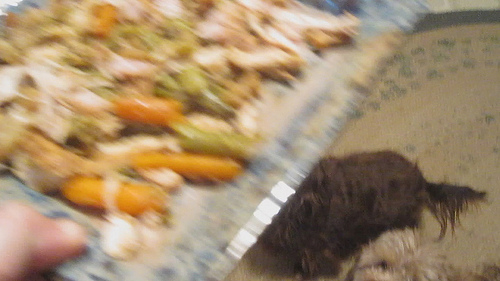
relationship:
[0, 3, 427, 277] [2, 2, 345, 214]
pan full of food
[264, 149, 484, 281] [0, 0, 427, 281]
dog going under pan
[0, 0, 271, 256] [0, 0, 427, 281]
food on pan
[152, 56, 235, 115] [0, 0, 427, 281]
broccoli on pan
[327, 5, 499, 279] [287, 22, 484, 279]
rug on floor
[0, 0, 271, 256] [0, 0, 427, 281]
food on a pan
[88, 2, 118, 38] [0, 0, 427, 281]
carrot on pan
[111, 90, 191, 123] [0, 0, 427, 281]
carrot on pan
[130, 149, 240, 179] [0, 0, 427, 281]
carrot on pan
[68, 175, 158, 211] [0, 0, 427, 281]
carrot on pan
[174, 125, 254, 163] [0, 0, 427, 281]
bean on pan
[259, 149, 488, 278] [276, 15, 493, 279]
dog on floor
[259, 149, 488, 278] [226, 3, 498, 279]
dog on floor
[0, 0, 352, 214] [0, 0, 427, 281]
chicken on pan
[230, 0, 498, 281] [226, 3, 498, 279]
rug on floor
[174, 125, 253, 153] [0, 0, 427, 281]
bean on pan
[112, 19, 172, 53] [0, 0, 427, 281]
broccoli on pan